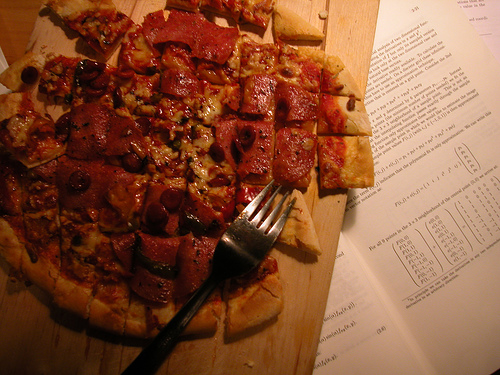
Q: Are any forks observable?
A: Yes, there is a fork.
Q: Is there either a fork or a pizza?
A: Yes, there is a fork.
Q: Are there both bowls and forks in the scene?
A: No, there is a fork but no bowls.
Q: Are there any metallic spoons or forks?
A: Yes, there is a metal fork.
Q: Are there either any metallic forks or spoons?
A: Yes, there is a metal fork.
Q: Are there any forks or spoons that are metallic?
A: Yes, the fork is metallic.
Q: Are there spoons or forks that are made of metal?
A: Yes, the fork is made of metal.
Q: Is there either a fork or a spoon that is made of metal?
A: Yes, the fork is made of metal.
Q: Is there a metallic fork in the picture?
A: Yes, there is a metal fork.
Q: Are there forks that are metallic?
A: Yes, there is a fork that is metallic.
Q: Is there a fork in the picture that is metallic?
A: Yes, there is a fork that is metallic.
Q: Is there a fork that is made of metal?
A: Yes, there is a fork that is made of metal.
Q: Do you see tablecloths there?
A: No, there are no tablecloths.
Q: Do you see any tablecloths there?
A: No, there are no tablecloths.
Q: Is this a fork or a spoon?
A: This is a fork.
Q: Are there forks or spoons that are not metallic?
A: No, there is a fork but it is metallic.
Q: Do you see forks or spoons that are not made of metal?
A: No, there is a fork but it is made of metal.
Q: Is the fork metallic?
A: Yes, the fork is metallic.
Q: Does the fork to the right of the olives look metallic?
A: Yes, the fork is metallic.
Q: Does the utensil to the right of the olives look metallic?
A: Yes, the fork is metallic.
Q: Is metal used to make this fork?
A: Yes, the fork is made of metal.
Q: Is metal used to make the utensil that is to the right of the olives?
A: Yes, the fork is made of metal.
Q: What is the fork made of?
A: The fork is made of metal.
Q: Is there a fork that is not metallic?
A: No, there is a fork but it is metallic.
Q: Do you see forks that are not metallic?
A: No, there is a fork but it is metallic.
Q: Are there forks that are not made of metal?
A: No, there is a fork but it is made of metal.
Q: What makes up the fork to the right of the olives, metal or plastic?
A: The fork is made of metal.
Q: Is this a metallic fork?
A: Yes, this is a metallic fork.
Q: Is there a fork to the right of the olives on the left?
A: Yes, there is a fork to the right of the olives.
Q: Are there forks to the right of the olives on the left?
A: Yes, there is a fork to the right of the olives.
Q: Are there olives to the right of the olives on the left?
A: No, there is a fork to the right of the olives.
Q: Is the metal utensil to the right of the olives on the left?
A: Yes, the fork is to the right of the olives.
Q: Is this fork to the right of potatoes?
A: No, the fork is to the right of the olives.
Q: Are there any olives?
A: Yes, there are olives.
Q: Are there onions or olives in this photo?
A: Yes, there are olives.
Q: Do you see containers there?
A: No, there are no containers.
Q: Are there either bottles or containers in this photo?
A: No, there are no containers or bottles.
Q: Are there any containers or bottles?
A: No, there are no containers or bottles.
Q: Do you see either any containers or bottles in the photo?
A: No, there are no containers or bottles.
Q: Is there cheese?
A: Yes, there is cheese.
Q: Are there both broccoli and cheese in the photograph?
A: No, there is cheese but no broccoli.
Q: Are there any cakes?
A: No, there are no cakes.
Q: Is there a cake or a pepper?
A: No, there are no cakes or peppers.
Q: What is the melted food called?
A: The food is cheese.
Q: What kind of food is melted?
A: The food is cheese.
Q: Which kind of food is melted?
A: The food is cheese.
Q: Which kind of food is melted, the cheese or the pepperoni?
A: The cheese is melted.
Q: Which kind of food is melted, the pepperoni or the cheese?
A: The cheese is melted.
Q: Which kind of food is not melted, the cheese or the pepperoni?
A: The pepperoni is not melted.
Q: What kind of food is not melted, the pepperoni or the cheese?
A: The pepperoni is not melted.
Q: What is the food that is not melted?
A: The food is pepperoni.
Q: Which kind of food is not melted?
A: The food is pepperoni.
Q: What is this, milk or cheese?
A: This is cheese.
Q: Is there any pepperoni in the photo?
A: Yes, there is pepperoni.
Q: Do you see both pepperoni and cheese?
A: Yes, there are both pepperoni and cheese.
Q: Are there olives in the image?
A: Yes, there are olives.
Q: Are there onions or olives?
A: Yes, there are olives.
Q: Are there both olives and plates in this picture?
A: No, there are olives but no plates.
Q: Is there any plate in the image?
A: No, there are no plates.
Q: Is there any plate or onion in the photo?
A: No, there are no plates or onions.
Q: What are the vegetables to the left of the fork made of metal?
A: The vegetables are olives.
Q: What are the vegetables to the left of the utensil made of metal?
A: The vegetables are olives.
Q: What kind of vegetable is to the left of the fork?
A: The vegetables are olives.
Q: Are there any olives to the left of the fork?
A: Yes, there are olives to the left of the fork.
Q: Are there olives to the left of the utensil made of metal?
A: Yes, there are olives to the left of the fork.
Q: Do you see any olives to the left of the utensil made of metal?
A: Yes, there are olives to the left of the fork.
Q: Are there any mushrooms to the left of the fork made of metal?
A: No, there are olives to the left of the fork.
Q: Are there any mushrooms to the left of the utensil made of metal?
A: No, there are olives to the left of the fork.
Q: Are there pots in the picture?
A: No, there are no pots.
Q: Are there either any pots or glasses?
A: No, there are no pots or glasses.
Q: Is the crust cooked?
A: Yes, the crust is cooked.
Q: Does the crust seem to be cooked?
A: Yes, the crust is cooked.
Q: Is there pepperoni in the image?
A: Yes, there is pepperoni.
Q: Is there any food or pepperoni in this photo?
A: Yes, there is pepperoni.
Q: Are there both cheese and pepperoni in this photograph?
A: Yes, there are both pepperoni and cheese.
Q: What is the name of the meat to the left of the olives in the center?
A: The meat is pepperoni.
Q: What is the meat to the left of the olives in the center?
A: The meat is pepperoni.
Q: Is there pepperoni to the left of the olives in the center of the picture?
A: Yes, there is pepperoni to the left of the olives.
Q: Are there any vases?
A: No, there are no vases.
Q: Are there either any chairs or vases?
A: No, there are no vases or chairs.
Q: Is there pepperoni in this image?
A: Yes, there is pepperoni.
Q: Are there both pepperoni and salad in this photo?
A: No, there is pepperoni but no salad.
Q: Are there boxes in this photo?
A: No, there are no boxes.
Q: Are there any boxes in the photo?
A: No, there are no boxes.